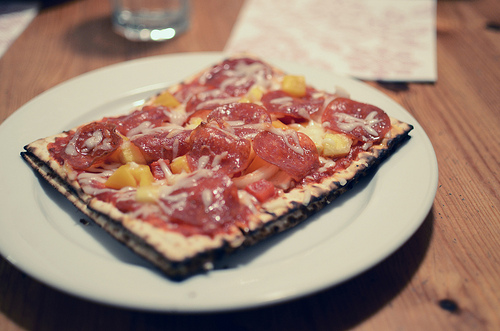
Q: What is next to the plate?
A: A glass.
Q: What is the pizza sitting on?
A: A white plate.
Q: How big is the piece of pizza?
A: Smaller than the plate.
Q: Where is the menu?
A: In front of the plate.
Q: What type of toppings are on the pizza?
A: Pepperoni and pineapple.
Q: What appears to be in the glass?
A: It looks empty.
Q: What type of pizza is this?
A: Flatbread.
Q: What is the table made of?
A: Wood.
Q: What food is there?
A: Pizza.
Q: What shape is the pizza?
A: Rectangular.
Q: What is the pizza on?
A: Plate.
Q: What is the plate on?
A: Table.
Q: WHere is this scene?
A: Restaurant.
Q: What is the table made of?
A: Wood.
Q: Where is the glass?
A: Left.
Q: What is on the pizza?
A: Pepperoni.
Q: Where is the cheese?
A: On top.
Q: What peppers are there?
A: Bananas.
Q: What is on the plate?
A: Pizza.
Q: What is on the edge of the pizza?
A: Burnt edges.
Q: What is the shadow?
A: The plate.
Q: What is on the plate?
A: Pizza.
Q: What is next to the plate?
A: A napkin.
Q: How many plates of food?
A: One.